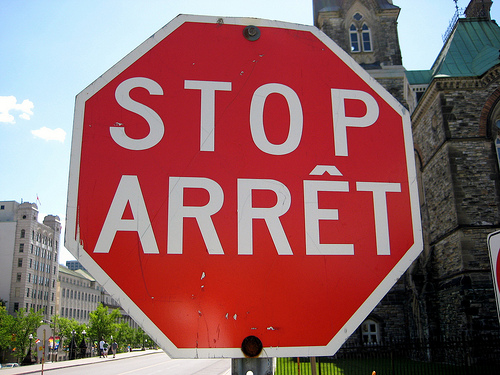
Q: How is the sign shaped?
A: Octagon.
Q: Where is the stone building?
A: Behind sign.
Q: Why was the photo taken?
A: To show a sign.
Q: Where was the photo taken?
A: City street.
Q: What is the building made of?
A: Old brick.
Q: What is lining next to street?
A: Trees.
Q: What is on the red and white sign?
A: STOP ARRET.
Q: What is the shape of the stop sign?
A: Octagon.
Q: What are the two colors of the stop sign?
A: Red and white.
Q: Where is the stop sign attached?
A: Pole.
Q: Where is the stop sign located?
A: Next to the street.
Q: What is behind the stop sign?
A: Old building.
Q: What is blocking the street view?
A: Stop sign.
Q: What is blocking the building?
A: Stop sign.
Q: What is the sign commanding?
A: Stop.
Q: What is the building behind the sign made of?
A: Brick.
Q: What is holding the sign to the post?
A: Nut and bolts.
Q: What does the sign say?
A: "Stop.".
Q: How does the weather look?
A: Sunny.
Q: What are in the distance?
A: Buildings.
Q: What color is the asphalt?
A: Grey.